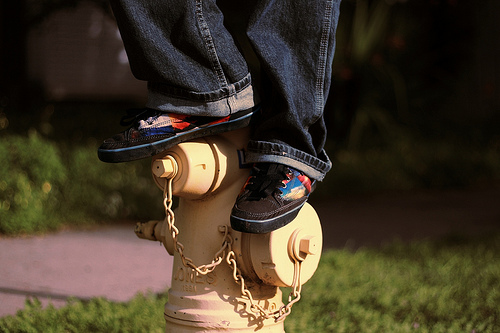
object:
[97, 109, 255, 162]
shoe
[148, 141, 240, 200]
bolts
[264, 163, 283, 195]
shoestrings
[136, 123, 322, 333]
hydrant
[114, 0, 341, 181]
jeans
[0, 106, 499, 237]
grass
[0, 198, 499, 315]
sidewalk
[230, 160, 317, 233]
shoe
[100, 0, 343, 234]
kid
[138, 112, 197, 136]
design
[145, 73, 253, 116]
cuffs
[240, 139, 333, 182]
cuffs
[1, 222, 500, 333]
lawn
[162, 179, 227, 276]
chain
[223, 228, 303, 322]
chain